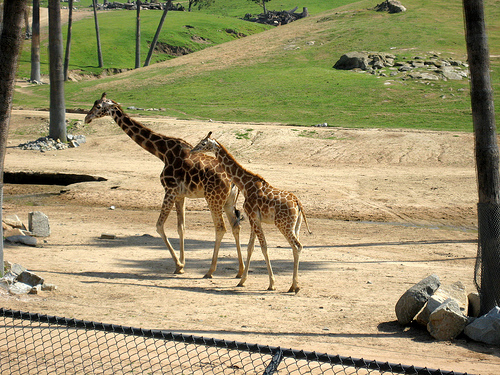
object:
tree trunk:
[132, 0, 141, 70]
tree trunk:
[142, 0, 174, 68]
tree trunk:
[46, 0, 69, 147]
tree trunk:
[28, 0, 43, 85]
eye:
[94, 100, 104, 110]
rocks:
[391, 272, 498, 351]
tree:
[462, 5, 499, 304]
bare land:
[12, 115, 473, 374]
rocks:
[18, 126, 99, 166]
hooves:
[235, 280, 301, 292]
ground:
[330, 144, 395, 198]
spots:
[172, 157, 209, 184]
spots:
[249, 185, 279, 213]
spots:
[114, 109, 193, 169]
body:
[84, 91, 228, 277]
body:
[188, 129, 312, 292]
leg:
[238, 204, 257, 286]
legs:
[233, 203, 274, 292]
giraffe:
[188, 128, 313, 292]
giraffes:
[83, 76, 323, 300]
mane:
[214, 138, 265, 181]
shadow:
[62, 211, 304, 296]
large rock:
[330, 45, 475, 99]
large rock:
[429, 297, 466, 337]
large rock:
[465, 303, 498, 340]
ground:
[312, 152, 430, 232]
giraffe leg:
[281, 227, 303, 293]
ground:
[356, 110, 399, 152]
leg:
[202, 200, 226, 281]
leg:
[152, 187, 187, 277]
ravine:
[5, 0, 337, 100]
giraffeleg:
[256, 227, 278, 291]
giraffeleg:
[173, 195, 192, 268]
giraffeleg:
[155, 195, 182, 271]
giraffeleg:
[211, 200, 227, 278]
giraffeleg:
[279, 232, 304, 295]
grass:
[238, 48, 359, 101]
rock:
[23, 213, 53, 244]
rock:
[397, 280, 498, 350]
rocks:
[332, 44, 469, 86]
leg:
[246, 206, 281, 292]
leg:
[221, 189, 251, 279]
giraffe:
[84, 90, 253, 282]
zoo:
[6, 3, 496, 369]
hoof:
[235, 281, 248, 290]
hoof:
[266, 280, 280, 291]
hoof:
[288, 286, 294, 293]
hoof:
[293, 286, 301, 296]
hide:
[113, 111, 243, 223]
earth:
[18, 5, 492, 369]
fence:
[3, 310, 484, 373]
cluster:
[386, 270, 494, 353]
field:
[6, 6, 492, 371]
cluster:
[327, 38, 492, 110]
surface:
[16, 166, 491, 367]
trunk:
[6, 3, 24, 187]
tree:
[0, 0, 38, 174]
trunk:
[31, 4, 44, 73]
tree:
[16, 3, 47, 82]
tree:
[25, 4, 86, 144]